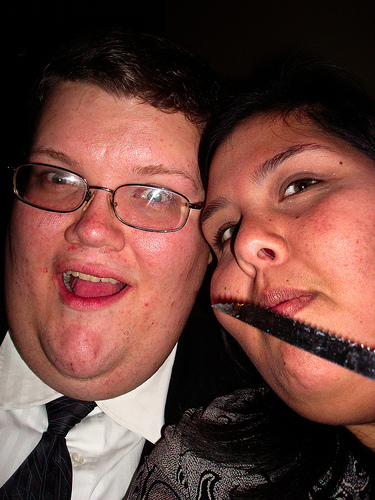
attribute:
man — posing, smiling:
[19, 64, 206, 405]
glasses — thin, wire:
[7, 156, 198, 231]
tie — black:
[11, 396, 95, 499]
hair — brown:
[42, 30, 222, 106]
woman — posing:
[203, 94, 374, 417]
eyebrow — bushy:
[239, 141, 342, 181]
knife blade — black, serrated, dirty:
[208, 298, 374, 393]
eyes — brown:
[216, 176, 330, 255]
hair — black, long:
[194, 69, 372, 145]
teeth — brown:
[63, 270, 119, 286]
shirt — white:
[0, 367, 118, 498]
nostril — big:
[252, 246, 276, 264]